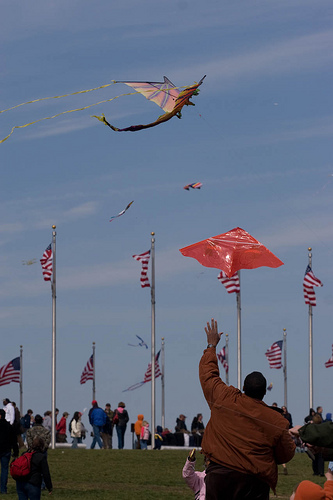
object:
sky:
[0, 2, 332, 454]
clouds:
[0, 52, 90, 152]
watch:
[206, 343, 216, 349]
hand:
[204, 317, 224, 346]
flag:
[38, 240, 54, 285]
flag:
[78, 346, 95, 386]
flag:
[302, 262, 324, 308]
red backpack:
[9, 449, 34, 481]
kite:
[107, 199, 135, 222]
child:
[180, 445, 210, 498]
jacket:
[181, 456, 206, 499]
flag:
[131, 248, 152, 288]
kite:
[178, 226, 284, 280]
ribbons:
[0, 79, 133, 149]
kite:
[183, 181, 203, 191]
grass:
[80, 449, 152, 475]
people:
[87, 399, 107, 449]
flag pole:
[50, 224, 57, 450]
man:
[198, 317, 297, 498]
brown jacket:
[198, 345, 297, 494]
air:
[0, 0, 326, 252]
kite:
[126, 331, 149, 349]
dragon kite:
[0, 74, 207, 146]